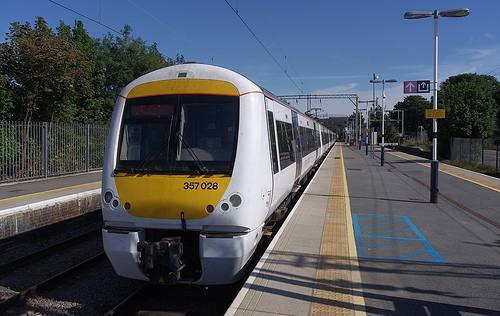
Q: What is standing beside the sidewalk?
A: Light.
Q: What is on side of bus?
A: Window.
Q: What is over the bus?
A: Power line.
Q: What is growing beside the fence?
A: Trees.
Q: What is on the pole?
A: Sign.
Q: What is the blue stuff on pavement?
A: Paint.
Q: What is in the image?
A: Train.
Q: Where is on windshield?
A: Train.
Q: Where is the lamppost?
A: Widewalk.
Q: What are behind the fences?
A: Trees.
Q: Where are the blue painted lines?
A: On the pavement.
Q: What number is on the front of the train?
A: 357028.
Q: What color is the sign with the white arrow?
A: Red.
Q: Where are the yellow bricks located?
A: On the sidewalks.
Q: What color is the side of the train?
A: White.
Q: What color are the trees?
A: Green.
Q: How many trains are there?
A: One.